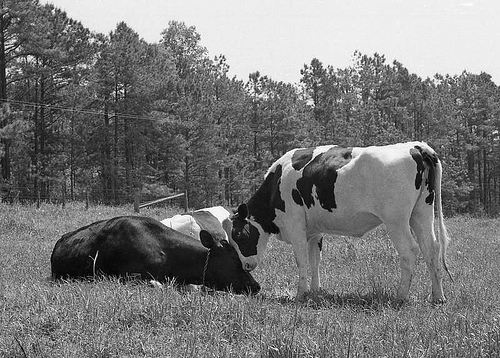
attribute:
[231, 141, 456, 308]
cow — black, white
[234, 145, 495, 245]
cow — brown, white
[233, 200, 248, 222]
ear — black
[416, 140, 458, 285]
tail — long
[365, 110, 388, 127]
ground — white, spotted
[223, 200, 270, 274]
head — cows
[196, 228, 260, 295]
head — cows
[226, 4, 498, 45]
sky — clear, bright, cloudless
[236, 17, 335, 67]
sky — overcast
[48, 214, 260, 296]
cow — black, resting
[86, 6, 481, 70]
sky — white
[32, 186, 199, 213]
posts — wood 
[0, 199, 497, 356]
field — lush, grassy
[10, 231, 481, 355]
field — grass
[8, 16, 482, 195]
trees — tall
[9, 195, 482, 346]
field — grassy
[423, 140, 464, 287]
tail — hanging, cows